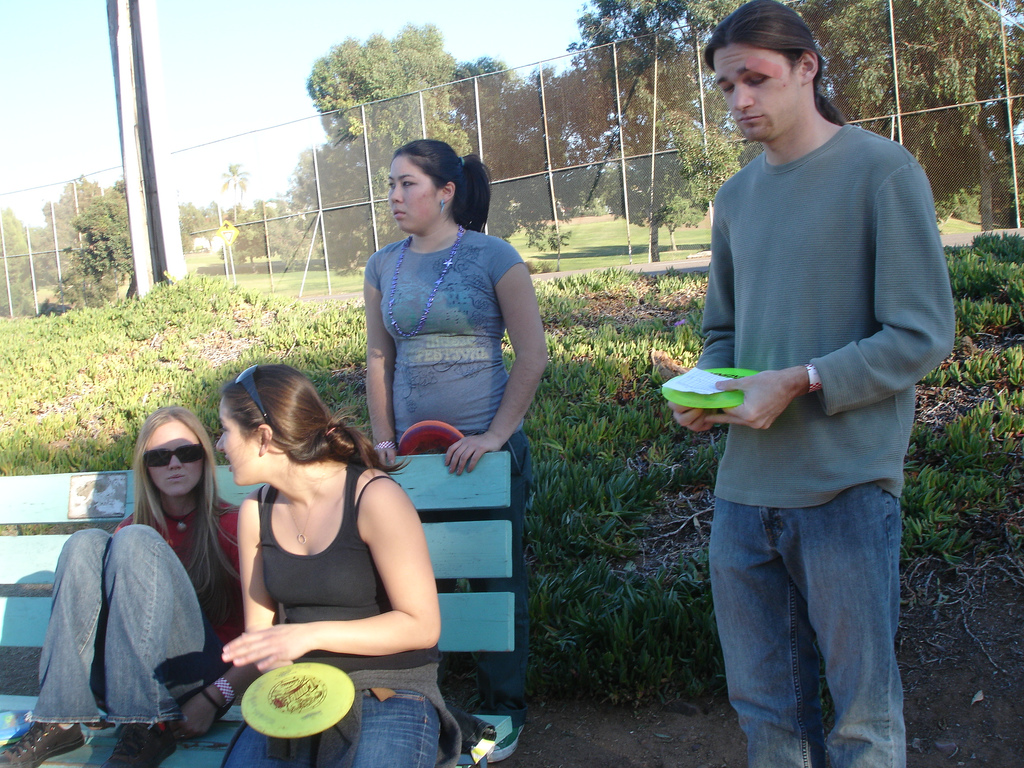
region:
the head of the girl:
[127, 402, 210, 523]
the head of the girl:
[216, 361, 327, 476]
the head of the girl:
[384, 145, 461, 235]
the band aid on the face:
[735, 50, 784, 80]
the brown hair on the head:
[222, 363, 385, 472]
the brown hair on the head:
[396, 131, 495, 231]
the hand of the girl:
[374, 440, 400, 466]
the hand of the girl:
[443, 431, 507, 473]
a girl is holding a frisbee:
[242, 661, 356, 741]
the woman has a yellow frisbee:
[242, 670, 356, 740]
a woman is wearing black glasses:
[147, 439, 204, 466]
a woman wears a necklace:
[385, 233, 462, 348]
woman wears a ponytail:
[458, 161, 494, 229]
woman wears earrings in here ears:
[442, 199, 446, 213]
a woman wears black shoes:
[5, 717, 167, 762]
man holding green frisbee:
[656, 2, 973, 762]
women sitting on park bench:
[0, 359, 504, 765]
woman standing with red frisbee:
[353, 131, 541, 758]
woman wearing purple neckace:
[357, 128, 553, 764]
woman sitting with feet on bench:
[1, 404, 239, 765]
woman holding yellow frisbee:
[212, 357, 460, 765]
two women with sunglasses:
[0, 357, 454, 765]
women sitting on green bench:
[1, 360, 511, 765]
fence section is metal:
[361, 85, 426, 196]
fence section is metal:
[423, 78, 478, 173]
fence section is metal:
[474, 60, 550, 177]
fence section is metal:
[542, 46, 622, 167]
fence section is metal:
[610, 24, 705, 155]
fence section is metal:
[550, 158, 631, 247]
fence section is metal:
[484, 166, 554, 250]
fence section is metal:
[620, 145, 700, 240]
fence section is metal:
[891, 2, 1010, 116]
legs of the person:
[701, 478, 951, 704]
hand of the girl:
[220, 622, 401, 695]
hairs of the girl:
[252, 389, 442, 473]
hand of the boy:
[723, 325, 818, 446]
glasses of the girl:
[142, 405, 251, 478]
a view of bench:
[436, 458, 545, 645]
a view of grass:
[565, 313, 698, 528]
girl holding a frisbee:
[224, 653, 360, 745]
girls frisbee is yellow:
[226, 647, 359, 750]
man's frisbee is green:
[651, 340, 776, 436]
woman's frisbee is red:
[390, 406, 474, 479]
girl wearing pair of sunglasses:
[136, 432, 207, 471]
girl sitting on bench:
[177, 349, 476, 765]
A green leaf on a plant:
[572, 310, 596, 327]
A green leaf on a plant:
[584, 432, 591, 445]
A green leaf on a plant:
[532, 497, 548, 508]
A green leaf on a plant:
[569, 461, 577, 475]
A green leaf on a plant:
[89, 328, 105, 338]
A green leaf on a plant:
[45, 433, 68, 443]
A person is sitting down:
[196, 378, 468, 755]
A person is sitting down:
[8, 403, 247, 749]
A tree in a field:
[283, 5, 479, 281]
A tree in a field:
[430, 49, 561, 290]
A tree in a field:
[587, 16, 723, 291]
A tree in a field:
[844, 13, 1003, 244]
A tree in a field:
[63, 198, 165, 328]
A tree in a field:
[35, 162, 111, 277]